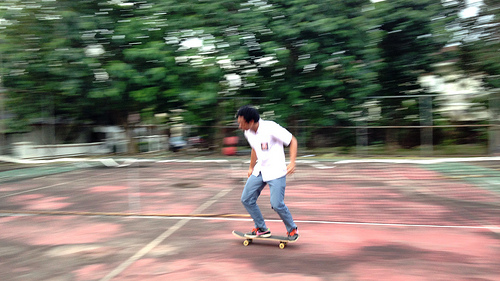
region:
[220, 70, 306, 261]
the man is skateboarding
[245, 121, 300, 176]
man's shirt is white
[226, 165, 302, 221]
man's pants are blue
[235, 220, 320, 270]
the skateboard is black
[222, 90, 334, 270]
man is skateboarding on tennis court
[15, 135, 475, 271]
tennis court is red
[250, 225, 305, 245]
shoe laces on shoe are red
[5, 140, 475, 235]
tennis net is white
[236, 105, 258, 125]
man's hair is black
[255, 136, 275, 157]
red logo on man's shirt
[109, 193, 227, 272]
the ground is red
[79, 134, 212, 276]
the ground is red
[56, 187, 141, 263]
the ground is red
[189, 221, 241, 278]
the ground is red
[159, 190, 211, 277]
the ground is red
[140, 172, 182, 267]
the ground is red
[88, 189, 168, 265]
the ground is red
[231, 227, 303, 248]
Skateboard under the man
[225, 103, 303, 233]
Man in white shirt on the skateboard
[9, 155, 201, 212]
Net on a tennis court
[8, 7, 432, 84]
Green trees in the background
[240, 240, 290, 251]
Yellow wheels under the skateboard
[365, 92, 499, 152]
Wire fence around the court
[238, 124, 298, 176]
Man is wearing a white shirt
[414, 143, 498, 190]
Perimeter of court is green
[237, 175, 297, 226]
Man in blue jeans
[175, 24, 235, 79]
Sky visible behind trees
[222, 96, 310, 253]
skater on a flat surface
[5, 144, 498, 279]
curt is red with white lines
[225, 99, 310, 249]
person wears white shirt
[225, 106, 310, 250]
skater wears blue jeans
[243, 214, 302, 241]
person wears person red socks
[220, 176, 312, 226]
skater has knees bended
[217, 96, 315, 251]
man faces left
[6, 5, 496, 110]
trees behind the court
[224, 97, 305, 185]
hands of man are on side of body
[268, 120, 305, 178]
arm is bend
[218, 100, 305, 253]
A man riding a skateboard.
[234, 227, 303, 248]
A black moving skateboard.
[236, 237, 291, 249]
A set of yellow wheels.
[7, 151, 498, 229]
A white tennis court net.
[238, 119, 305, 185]
A white shirt with a collar.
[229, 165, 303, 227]
Blue men's jeans.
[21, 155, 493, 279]
A red tennis court.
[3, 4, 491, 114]
Trees behind a tennis court.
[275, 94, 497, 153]
A chain link fence.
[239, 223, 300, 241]
Tennis shoes with red laces.